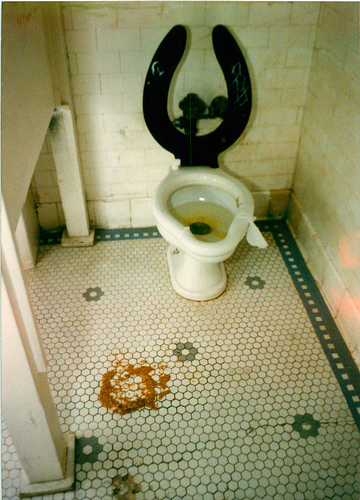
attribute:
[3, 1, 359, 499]
bathroom — public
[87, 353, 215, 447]
vomit — orange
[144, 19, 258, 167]
toilet seat — round, black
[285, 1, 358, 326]
tile wall — white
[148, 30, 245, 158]
seat — up, black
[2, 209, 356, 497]
floor tiles — white, green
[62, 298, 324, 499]
floor — patterned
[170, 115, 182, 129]
toilet handle — black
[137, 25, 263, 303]
toilet — dirty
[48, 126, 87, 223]
leg — dirty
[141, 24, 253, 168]
toilet seat — white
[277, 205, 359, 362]
base — white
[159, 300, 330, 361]
floor tiles — white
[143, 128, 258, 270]
toilet — white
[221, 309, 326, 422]
tile — green, white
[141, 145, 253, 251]
toilet — dirty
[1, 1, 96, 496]
divider — white